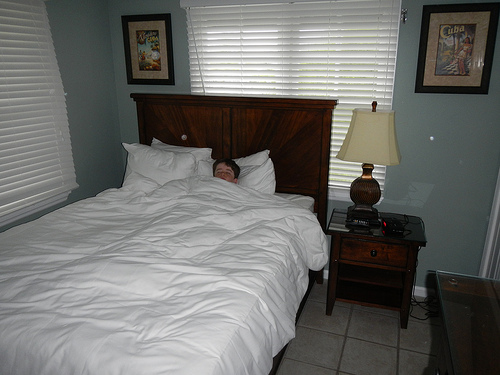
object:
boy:
[210, 159, 243, 184]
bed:
[4, 92, 340, 374]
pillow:
[198, 147, 277, 197]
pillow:
[119, 141, 195, 188]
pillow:
[151, 135, 212, 177]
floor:
[276, 281, 431, 375]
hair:
[212, 158, 244, 177]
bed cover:
[0, 172, 330, 374]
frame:
[268, 268, 322, 375]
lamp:
[337, 99, 405, 204]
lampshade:
[335, 109, 407, 168]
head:
[211, 156, 241, 185]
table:
[324, 206, 428, 329]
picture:
[119, 13, 179, 87]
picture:
[416, 0, 498, 95]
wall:
[108, 0, 499, 285]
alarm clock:
[380, 217, 406, 236]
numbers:
[380, 219, 391, 228]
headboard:
[128, 91, 337, 198]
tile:
[277, 281, 431, 375]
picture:
[0, 0, 498, 374]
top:
[327, 206, 428, 247]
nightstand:
[327, 206, 429, 328]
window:
[186, 6, 403, 191]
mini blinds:
[178, 2, 403, 197]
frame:
[119, 15, 176, 86]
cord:
[402, 215, 432, 322]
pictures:
[122, 2, 499, 96]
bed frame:
[269, 265, 317, 374]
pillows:
[120, 135, 278, 196]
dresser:
[325, 208, 428, 327]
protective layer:
[330, 206, 428, 242]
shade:
[181, 2, 404, 204]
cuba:
[438, 23, 469, 43]